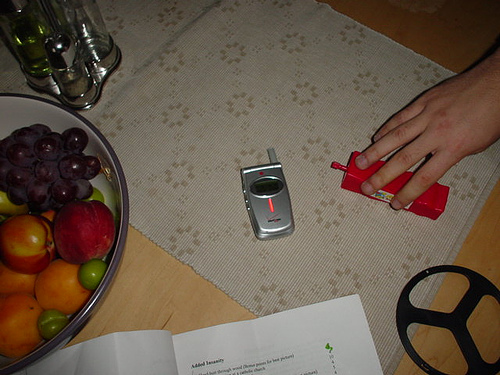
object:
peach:
[53, 199, 116, 264]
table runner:
[1, 3, 498, 374]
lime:
[79, 258, 107, 290]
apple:
[0, 213, 59, 275]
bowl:
[0, 92, 129, 375]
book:
[20, 292, 382, 374]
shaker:
[0, 0, 123, 110]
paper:
[14, 293, 384, 374]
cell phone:
[240, 148, 295, 242]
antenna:
[266, 148, 278, 164]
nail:
[362, 182, 375, 195]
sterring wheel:
[395, 264, 500, 375]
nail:
[355, 154, 368, 167]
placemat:
[0, 0, 500, 375]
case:
[330, 150, 450, 220]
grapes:
[0, 121, 103, 214]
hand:
[354, 49, 500, 211]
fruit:
[0, 120, 121, 359]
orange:
[35, 259, 92, 315]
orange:
[1, 267, 36, 295]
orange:
[1, 294, 43, 358]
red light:
[268, 197, 274, 212]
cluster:
[0, 123, 102, 215]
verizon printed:
[268, 213, 281, 224]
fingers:
[355, 91, 461, 210]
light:
[268, 197, 275, 212]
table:
[0, 0, 493, 375]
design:
[225, 91, 255, 118]